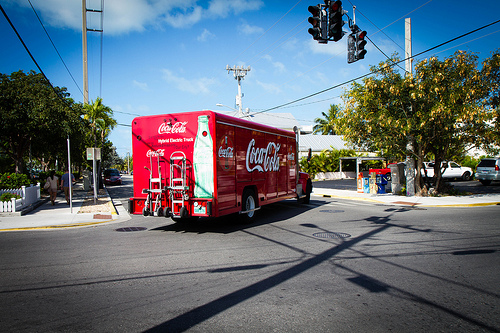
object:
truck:
[129, 108, 313, 225]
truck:
[415, 158, 473, 182]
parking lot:
[312, 174, 497, 198]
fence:
[2, 181, 42, 216]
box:
[369, 174, 377, 194]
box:
[376, 174, 387, 193]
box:
[356, 170, 363, 192]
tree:
[315, 51, 499, 194]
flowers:
[369, 86, 387, 99]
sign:
[87, 146, 100, 161]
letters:
[242, 136, 282, 172]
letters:
[157, 118, 189, 136]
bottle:
[192, 114, 214, 199]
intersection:
[95, 201, 429, 257]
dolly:
[143, 149, 163, 218]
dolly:
[168, 148, 187, 218]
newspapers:
[369, 178, 375, 184]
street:
[3, 216, 494, 327]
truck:
[474, 155, 500, 184]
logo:
[145, 147, 167, 159]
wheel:
[242, 190, 258, 221]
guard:
[239, 206, 260, 214]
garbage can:
[81, 176, 93, 192]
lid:
[83, 175, 90, 179]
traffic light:
[305, 3, 330, 45]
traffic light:
[329, 0, 345, 40]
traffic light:
[355, 29, 367, 60]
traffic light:
[347, 32, 355, 60]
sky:
[103, 1, 220, 107]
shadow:
[144, 212, 421, 329]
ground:
[18, 218, 496, 328]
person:
[43, 168, 61, 206]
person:
[62, 166, 77, 205]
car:
[105, 168, 123, 185]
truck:
[369, 163, 399, 181]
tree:
[2, 66, 53, 161]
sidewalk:
[6, 174, 103, 228]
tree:
[80, 97, 113, 130]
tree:
[97, 113, 117, 155]